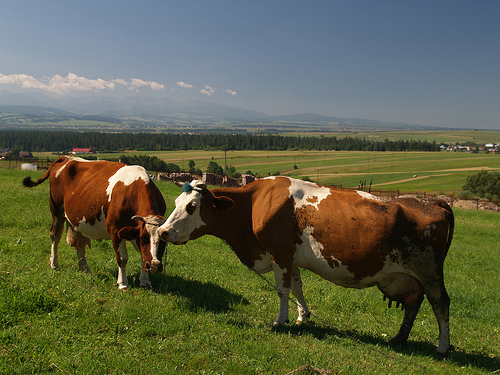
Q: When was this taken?
A: During the day.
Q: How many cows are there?
A: Two.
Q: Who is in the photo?
A: No one.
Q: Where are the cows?
A: In a grassy field.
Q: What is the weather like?
A: Sunny.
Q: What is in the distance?
A: Fields and mountains.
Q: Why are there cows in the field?
A: To graze.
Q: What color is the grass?
A: Green.